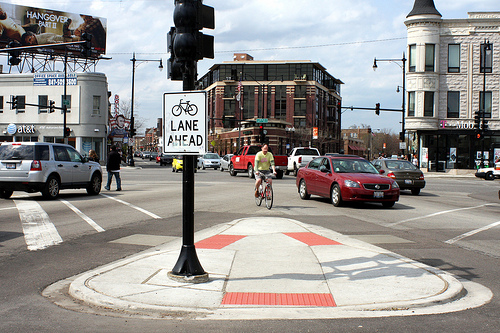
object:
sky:
[243, 3, 337, 43]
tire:
[329, 184, 340, 206]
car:
[301, 154, 399, 205]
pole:
[181, 80, 197, 244]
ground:
[128, 253, 244, 321]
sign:
[164, 91, 209, 154]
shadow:
[209, 252, 477, 283]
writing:
[198, 135, 203, 144]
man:
[254, 145, 274, 196]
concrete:
[266, 245, 305, 286]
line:
[100, 190, 159, 220]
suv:
[229, 143, 284, 178]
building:
[200, 47, 347, 166]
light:
[257, 126, 264, 130]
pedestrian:
[106, 147, 122, 188]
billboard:
[3, 2, 109, 58]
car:
[0, 139, 104, 196]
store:
[404, 127, 496, 175]